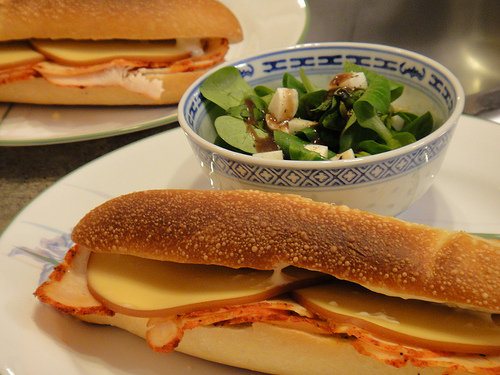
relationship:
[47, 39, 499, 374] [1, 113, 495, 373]
food on a plate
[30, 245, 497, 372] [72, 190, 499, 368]
meat on hoagie roll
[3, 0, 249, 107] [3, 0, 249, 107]
hoagie roll on hoagie roll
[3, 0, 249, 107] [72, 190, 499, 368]
hoagie roll on hoagie roll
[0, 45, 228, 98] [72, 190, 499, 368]
meat on hoagie roll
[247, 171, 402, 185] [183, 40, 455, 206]
design on bowl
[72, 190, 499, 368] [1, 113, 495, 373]
hoagie roll on plate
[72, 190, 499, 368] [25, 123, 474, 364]
hoagie roll on plate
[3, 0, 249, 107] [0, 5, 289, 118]
hoagie roll on plate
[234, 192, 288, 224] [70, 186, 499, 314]
seeds are on bread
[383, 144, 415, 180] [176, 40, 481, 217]
design on bowl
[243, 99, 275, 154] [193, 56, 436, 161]
dressing on salad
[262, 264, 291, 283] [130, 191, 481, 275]
mayo on bread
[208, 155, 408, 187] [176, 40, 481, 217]
decoration on bowl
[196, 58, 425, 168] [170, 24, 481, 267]
salad in bowl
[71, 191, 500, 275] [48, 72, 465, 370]
bread on plate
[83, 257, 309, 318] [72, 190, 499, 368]
cheese on hoagie roll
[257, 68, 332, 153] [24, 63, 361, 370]
flower on plate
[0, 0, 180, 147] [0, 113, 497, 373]
plate sandwich on white plate